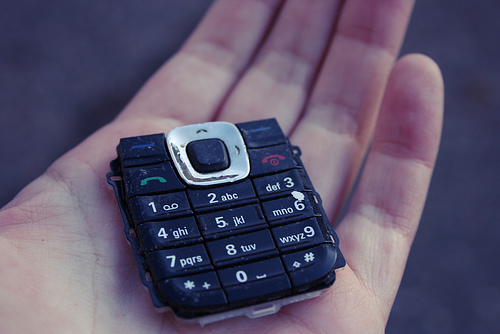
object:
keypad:
[105, 116, 345, 327]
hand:
[0, 0, 446, 334]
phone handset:
[140, 176, 167, 186]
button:
[122, 161, 185, 200]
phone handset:
[262, 154, 285, 165]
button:
[246, 144, 299, 179]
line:
[250, 126, 272, 132]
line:
[131, 143, 155, 149]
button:
[236, 117, 288, 149]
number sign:
[303, 252, 315, 262]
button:
[280, 243, 338, 289]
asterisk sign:
[183, 279, 195, 289]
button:
[155, 270, 227, 314]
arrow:
[196, 128, 207, 133]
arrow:
[234, 145, 240, 155]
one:
[148, 201, 157, 212]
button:
[128, 189, 193, 225]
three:
[284, 177, 295, 188]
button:
[252, 168, 315, 200]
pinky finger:
[331, 53, 448, 288]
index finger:
[126, 0, 286, 127]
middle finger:
[212, 0, 343, 139]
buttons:
[195, 203, 269, 240]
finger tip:
[386, 50, 445, 91]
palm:
[14, 183, 154, 333]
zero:
[235, 270, 248, 282]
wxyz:
[278, 233, 306, 243]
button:
[270, 216, 332, 254]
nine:
[304, 226, 315, 238]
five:
[215, 216, 227, 228]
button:
[195, 202, 269, 241]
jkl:
[233, 215, 246, 226]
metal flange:
[106, 163, 161, 316]